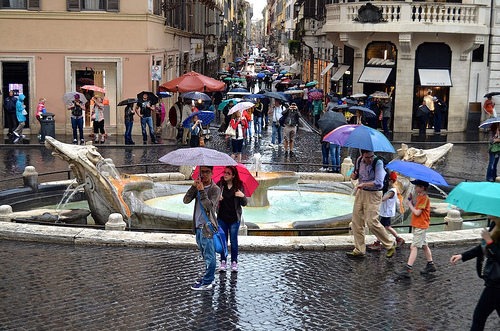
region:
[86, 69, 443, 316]
people with umbrellas in town's center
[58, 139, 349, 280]
fountain behind women with umbrellas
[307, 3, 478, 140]
store made of white stone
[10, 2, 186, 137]
peach colored stone building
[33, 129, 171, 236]
grey cement fountain head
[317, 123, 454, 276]
man walking with children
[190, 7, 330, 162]
heavily-traveled city side street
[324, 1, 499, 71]
balcony above shop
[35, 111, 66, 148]
grey trash can on sidewalk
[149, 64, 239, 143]
large red umbella on corner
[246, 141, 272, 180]
Water in a fountain.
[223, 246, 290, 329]
Reflection on the ground.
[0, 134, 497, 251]
Water fountain in the square.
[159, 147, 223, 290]
Man holding an umbrella looking at the camera.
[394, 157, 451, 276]
Little boy holding an umbrella.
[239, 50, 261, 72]
A car in the background.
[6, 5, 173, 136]
The building is beige.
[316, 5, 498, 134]
The building is tan.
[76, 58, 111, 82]
Dior on a window.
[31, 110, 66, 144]
Trashcan in front of the building.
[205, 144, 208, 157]
part of an umbrella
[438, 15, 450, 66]
part of a balcony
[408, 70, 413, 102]
edge of a building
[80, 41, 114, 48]
part of a building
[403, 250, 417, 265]
leg of a boy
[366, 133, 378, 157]
face of a man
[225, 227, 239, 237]
thighs of a woman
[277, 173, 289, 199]
part of a sprinkler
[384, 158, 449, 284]
Young boy wearing blue umbrella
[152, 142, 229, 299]
Man holding a gray umbrella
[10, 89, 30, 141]
Woman wearing a blue raincoat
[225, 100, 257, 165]
Woman holding a white umbrella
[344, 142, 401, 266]
Man looking at young boy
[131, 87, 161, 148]
Man holding a black umbrella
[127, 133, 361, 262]
Water fountain behind people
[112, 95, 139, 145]
Woman holding a black umbrella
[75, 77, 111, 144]
Woman wearing a brown jacket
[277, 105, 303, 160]
Man wearing tan shorts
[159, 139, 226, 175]
umbrella for rain protection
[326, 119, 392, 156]
umbrella for rain protection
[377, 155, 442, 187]
umbrella for rain protection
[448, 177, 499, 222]
umbrella for rain protection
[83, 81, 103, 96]
umbrella for rain protection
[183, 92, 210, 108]
umbrella for rain protection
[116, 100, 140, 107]
umbrella for rain protection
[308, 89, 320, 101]
umbrella for rain protection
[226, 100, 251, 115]
umbrella for rain protection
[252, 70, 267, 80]
umbrella for rain protection